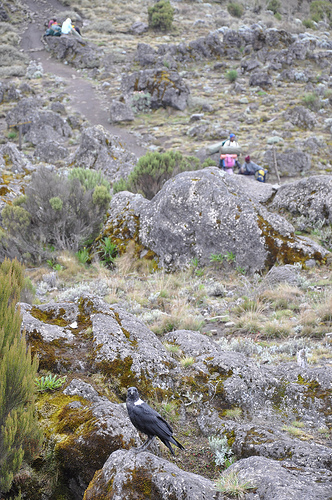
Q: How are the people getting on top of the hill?
A: Walking.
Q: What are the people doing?
A: Resting.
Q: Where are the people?
A: Sitting on the side of the mountain.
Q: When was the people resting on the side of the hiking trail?
A: Mid morning.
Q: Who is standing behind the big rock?
A: A woman in a blue scarf.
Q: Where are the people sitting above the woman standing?
A: Beside a trail.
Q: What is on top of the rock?
A: A black crow.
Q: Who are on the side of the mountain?
A: Four people.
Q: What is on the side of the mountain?
A: Gray rocks.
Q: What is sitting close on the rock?
A: A bird.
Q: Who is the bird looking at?
A: The photographer.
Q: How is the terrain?
A: Rocky.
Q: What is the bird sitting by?
A: A tree.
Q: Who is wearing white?
A: A hiker.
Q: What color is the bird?
A: Black and white.